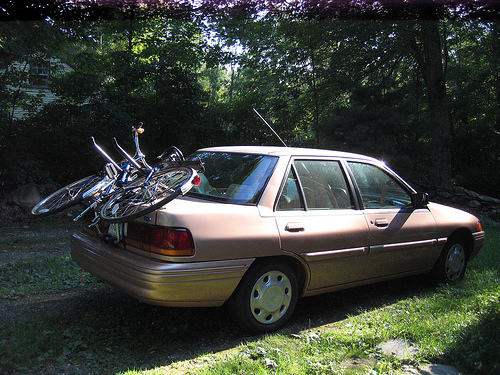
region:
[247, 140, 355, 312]
a car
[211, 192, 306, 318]
a car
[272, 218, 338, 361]
a car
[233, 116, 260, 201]
a car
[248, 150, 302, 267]
a car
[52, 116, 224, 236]
bicycles on the back of a car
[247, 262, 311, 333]
silver rim of a car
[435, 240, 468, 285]
silver rim of a car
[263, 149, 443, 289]
side doors on a car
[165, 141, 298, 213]
back windshield of a car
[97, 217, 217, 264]
rear tail lights of a car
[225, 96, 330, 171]
antennae on top of a car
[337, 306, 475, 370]
green grass on the ground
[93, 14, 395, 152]
green trees in the background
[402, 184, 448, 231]
side view mirror on a car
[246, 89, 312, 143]
antenna on the car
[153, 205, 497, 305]
shadow on bottom half of car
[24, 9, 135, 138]
building behind the trees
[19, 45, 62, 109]
window on the house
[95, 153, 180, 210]
bicycle is blue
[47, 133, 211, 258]
bicycle on the back of car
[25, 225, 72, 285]
gravel in the grass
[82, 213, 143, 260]
license plate for car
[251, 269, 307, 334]
hub cap for the tire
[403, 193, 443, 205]
right side mirror on the car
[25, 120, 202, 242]
bicycles mounted on car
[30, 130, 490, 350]
tan vehicle carrying bikes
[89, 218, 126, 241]
white license plate on car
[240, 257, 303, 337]
tire on rear of car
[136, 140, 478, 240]
sunshine on the car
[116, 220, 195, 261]
wide tail light on the car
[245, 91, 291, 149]
antenna on car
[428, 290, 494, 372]
shadow on the grass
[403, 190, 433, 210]
exterior rear view mirror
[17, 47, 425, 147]
trees on the background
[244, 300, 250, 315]
the tire is black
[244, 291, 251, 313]
the tire is black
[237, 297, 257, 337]
the tire is black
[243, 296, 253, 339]
the tire is black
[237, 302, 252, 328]
the tire is black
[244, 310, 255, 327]
the tire is black